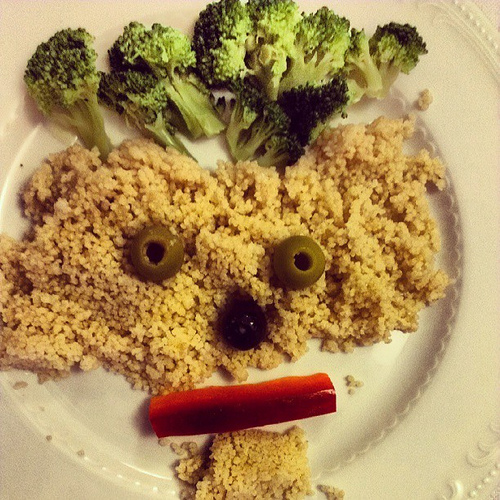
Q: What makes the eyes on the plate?
A: Olives.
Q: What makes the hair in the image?
A: Broccoli.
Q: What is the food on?
A: Plate.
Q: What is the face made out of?
A: Couscous.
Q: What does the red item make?
A: Mouth.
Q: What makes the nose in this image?
A: Black olive.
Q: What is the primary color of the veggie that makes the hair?
A: Green.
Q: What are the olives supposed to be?
A: Eyes.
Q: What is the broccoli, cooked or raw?
A: Cooked.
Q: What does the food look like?
A: Face.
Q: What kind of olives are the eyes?
A: Green.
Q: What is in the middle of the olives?
A: Holes.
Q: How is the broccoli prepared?
A: Cooked.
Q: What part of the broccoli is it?
A: Crown.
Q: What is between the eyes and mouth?
A: Nose.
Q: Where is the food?
A: On plate.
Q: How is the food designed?
A: As a face.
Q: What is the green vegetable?
A: Broccoli.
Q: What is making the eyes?
A: Olives.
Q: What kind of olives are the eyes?
A: Green olives.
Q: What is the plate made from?
A: Porcelain.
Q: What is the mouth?
A: A pepper.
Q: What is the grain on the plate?
A: Couscous.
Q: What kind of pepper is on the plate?
A: Red.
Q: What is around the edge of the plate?
A: Dots.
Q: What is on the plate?
A: Food.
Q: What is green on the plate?
A: Broccoli.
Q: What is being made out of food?
A: A face.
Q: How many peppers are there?
A: 1.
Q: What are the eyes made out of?
A: Olives.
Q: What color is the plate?
A: White.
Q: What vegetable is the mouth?
A: Pepper.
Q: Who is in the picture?
A: No one.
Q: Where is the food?
A: On a plate.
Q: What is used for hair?
A: Broccoli.